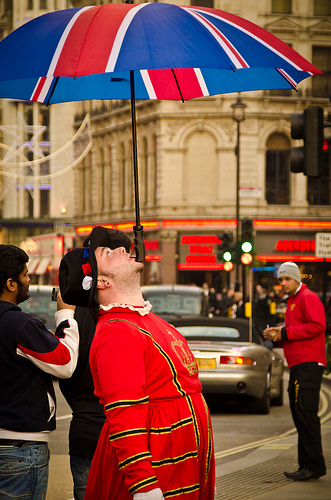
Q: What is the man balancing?
A: An umbrella.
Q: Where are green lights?
A: On traffic lights.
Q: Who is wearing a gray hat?
A: Man in red coat.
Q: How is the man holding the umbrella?
A: On his chin.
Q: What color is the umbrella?
A: Red, white and blue.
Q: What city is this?
A: London.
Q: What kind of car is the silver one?
A: Convertible.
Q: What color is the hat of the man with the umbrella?
A: Black.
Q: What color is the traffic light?
A: Green.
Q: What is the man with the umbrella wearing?
A: British guard costume.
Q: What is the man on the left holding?
A: Camera.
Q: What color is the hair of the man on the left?
A: Black.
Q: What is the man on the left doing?
A: Taking a picture.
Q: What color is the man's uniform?
A: Red.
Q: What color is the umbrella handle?
A: Black.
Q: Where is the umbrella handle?
A: On the man's chin.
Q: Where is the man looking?
A: At the umbrella.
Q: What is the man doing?
A: Balancing an umbrella.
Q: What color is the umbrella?
A: Red, blue, and white.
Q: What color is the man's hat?
A: Black.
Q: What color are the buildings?
A: Tan.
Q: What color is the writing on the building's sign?
A: Red.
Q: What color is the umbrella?
A: Red, white and blue.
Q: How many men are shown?
A: Three.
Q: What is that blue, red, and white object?
A: An umbrella.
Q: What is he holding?
A: An umbrella.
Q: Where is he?
A: In the street.